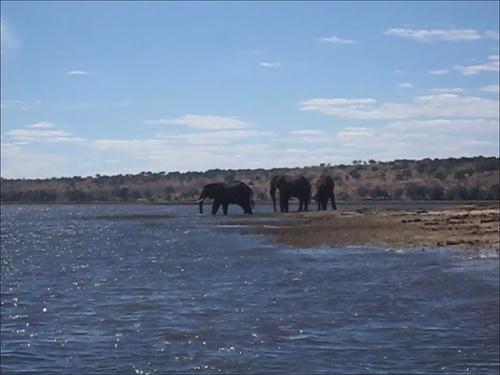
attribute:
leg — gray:
[209, 193, 233, 217]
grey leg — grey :
[281, 189, 293, 209]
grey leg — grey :
[280, 202, 290, 210]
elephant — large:
[191, 178, 259, 217]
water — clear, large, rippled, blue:
[3, 203, 483, 373]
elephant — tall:
[192, 176, 258, 220]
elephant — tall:
[269, 171, 314, 212]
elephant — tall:
[304, 166, 339, 217]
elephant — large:
[262, 170, 316, 218]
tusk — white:
[193, 197, 205, 207]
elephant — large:
[193, 177, 255, 218]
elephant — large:
[264, 174, 315, 221]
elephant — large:
[310, 165, 341, 218]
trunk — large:
[192, 195, 205, 217]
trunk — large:
[265, 190, 282, 212]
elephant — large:
[199, 179, 255, 216]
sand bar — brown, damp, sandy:
[221, 203, 499, 272]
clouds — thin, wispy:
[1, 22, 499, 177]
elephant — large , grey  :
[190, 180, 269, 221]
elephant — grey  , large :
[268, 166, 314, 223]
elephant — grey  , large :
[306, 166, 340, 215]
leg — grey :
[235, 190, 262, 220]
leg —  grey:
[297, 193, 307, 214]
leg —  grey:
[298, 194, 314, 213]